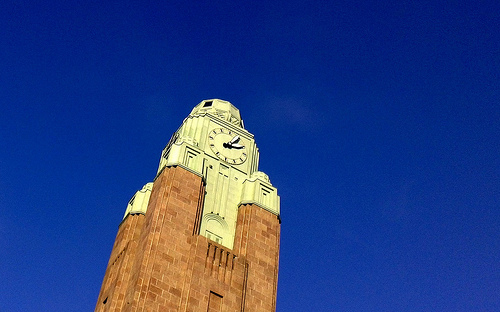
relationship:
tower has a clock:
[96, 98, 283, 309] [207, 124, 249, 165]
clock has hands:
[207, 124, 249, 165] [224, 136, 244, 151]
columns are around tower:
[93, 174, 280, 310] [96, 98, 283, 309]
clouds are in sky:
[265, 94, 309, 123] [1, 1, 500, 311]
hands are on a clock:
[224, 136, 244, 151] [207, 124, 249, 165]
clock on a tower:
[207, 124, 249, 165] [96, 98, 283, 309]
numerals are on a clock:
[208, 125, 248, 166] [207, 124, 249, 165]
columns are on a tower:
[93, 174, 280, 310] [96, 98, 283, 309]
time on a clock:
[209, 128, 248, 166] [207, 124, 249, 165]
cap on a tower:
[190, 99, 244, 122] [96, 98, 283, 309]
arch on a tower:
[203, 211, 229, 243] [96, 98, 283, 309]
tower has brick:
[96, 98, 283, 309] [97, 165, 280, 311]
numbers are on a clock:
[208, 126, 246, 166] [207, 124, 249, 165]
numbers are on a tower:
[208, 126, 246, 166] [96, 98, 283, 309]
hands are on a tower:
[224, 136, 244, 151] [96, 98, 283, 309]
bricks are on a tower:
[93, 166, 281, 309] [96, 98, 283, 309]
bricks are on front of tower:
[93, 166, 281, 309] [96, 98, 288, 309]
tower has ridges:
[96, 98, 283, 309] [205, 242, 239, 282]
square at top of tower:
[201, 98, 215, 109] [96, 98, 288, 309]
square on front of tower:
[201, 98, 215, 109] [96, 98, 283, 309]